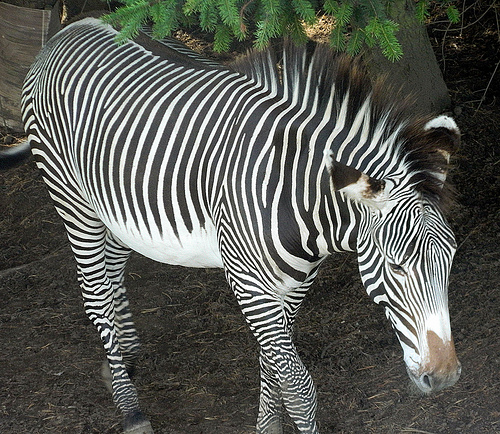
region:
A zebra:
[306, 9, 499, 300]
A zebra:
[188, 190, 302, 318]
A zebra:
[187, 152, 268, 320]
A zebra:
[170, 70, 287, 375]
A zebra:
[244, 167, 329, 404]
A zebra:
[200, 215, 317, 419]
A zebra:
[220, 150, 330, 385]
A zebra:
[200, 47, 305, 432]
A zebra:
[197, 182, 312, 422]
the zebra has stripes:
[7, 10, 487, 337]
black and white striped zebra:
[28, 22, 458, 427]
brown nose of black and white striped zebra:
[416, 320, 458, 392]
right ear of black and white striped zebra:
[322, 157, 387, 206]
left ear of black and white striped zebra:
[427, 112, 459, 202]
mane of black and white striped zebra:
[247, 40, 424, 151]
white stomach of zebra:
[117, 232, 209, 261]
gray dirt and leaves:
[13, 228, 60, 413]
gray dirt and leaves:
[152, 295, 232, 402]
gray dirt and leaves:
[326, 317, 386, 406]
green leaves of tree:
[136, 5, 388, 35]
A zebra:
[393, 249, 465, 341]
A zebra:
[271, 132, 307, 200]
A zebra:
[263, 166, 401, 404]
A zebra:
[296, 226, 373, 358]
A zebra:
[378, 170, 442, 332]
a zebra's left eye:
[375, 250, 417, 285]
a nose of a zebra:
[416, 352, 466, 402]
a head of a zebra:
[363, 210, 463, 391]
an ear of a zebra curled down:
[320, 145, 405, 210]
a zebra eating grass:
[4, 3, 495, 425]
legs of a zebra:
[65, 233, 328, 430]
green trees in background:
[109, 0, 496, 85]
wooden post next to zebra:
[0, 5, 55, 139]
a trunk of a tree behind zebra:
[348, 10, 455, 118]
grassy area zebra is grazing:
[11, 248, 488, 410]